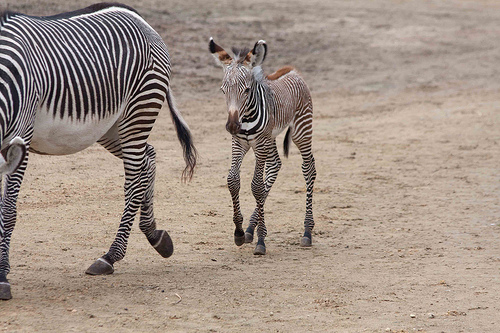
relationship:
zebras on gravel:
[4, 5, 327, 287] [2, 2, 497, 329]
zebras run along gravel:
[0, 2, 336, 312] [14, 124, 499, 329]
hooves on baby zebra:
[229, 232, 313, 258] [207, 33, 320, 257]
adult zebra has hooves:
[3, 3, 197, 303] [2, 230, 180, 303]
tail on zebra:
[163, 85, 199, 185] [3, 3, 197, 303]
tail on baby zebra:
[281, 126, 293, 157] [207, 33, 320, 257]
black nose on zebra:
[224, 120, 247, 136] [207, 33, 320, 257]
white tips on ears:
[205, 35, 267, 45] [205, 36, 267, 66]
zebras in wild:
[0, 2, 336, 312] [2, 2, 497, 329]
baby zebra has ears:
[207, 33, 320, 257] [205, 36, 267, 66]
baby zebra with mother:
[207, 33, 320, 257] [3, 3, 197, 303]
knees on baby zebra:
[225, 171, 269, 200] [207, 33, 320, 257]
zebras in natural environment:
[0, 2, 336, 312] [2, 2, 497, 329]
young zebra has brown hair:
[207, 33, 320, 257] [265, 65, 294, 81]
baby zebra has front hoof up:
[207, 33, 320, 257] [229, 225, 250, 248]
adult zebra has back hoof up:
[3, 3, 197, 303] [155, 229, 175, 262]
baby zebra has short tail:
[207, 33, 320, 257] [281, 126, 293, 157]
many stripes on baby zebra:
[224, 63, 316, 234] [207, 33, 320, 257]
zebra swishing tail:
[3, 3, 197, 303] [163, 85, 199, 185]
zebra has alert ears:
[207, 33, 320, 257] [205, 36, 267, 66]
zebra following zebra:
[207, 33, 320, 257] [3, 3, 197, 303]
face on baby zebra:
[206, 37, 272, 136] [207, 33, 320, 257]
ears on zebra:
[205, 36, 267, 66] [207, 33, 320, 257]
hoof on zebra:
[85, 257, 115, 278] [3, 3, 197, 303]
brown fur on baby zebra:
[265, 65, 294, 81] [207, 33, 320, 257]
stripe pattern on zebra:
[6, 12, 158, 267] [3, 3, 197, 303]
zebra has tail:
[3, 3, 197, 303] [163, 85, 199, 185]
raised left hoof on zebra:
[155, 229, 175, 262] [3, 3, 197, 303]